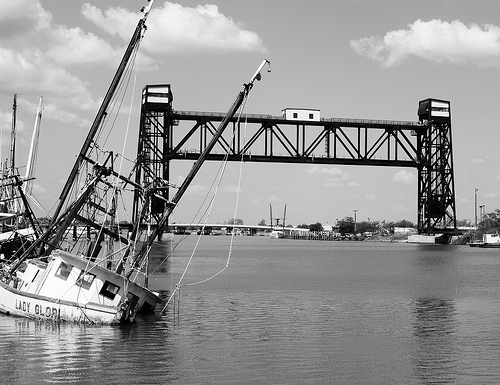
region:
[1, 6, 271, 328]
broken ship half under water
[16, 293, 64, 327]
Boat is named lady glori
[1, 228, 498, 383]
water is dark and calm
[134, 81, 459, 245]
boat pier and crane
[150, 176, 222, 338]
Ropes dragging in water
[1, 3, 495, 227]
sky is light and few clouds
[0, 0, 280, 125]
clouds are white and fluffy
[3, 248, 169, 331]
boats are white with windows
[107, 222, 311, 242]
bridge in background skyline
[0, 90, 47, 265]
boat behind the broken boat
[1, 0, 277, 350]
The ship is sinking.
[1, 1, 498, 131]
White clouds in sky.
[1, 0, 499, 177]
White clouds are puffy.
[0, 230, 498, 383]
The water is calm.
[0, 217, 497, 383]
The water is serene.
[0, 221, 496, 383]
The water is tranquil.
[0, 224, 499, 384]
The water is sedate.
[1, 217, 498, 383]
The water is ripply.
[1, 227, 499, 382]
The water is pleasant.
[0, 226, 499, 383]
The water is subdued.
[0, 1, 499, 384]
calm clear water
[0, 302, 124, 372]
shadow of boat in water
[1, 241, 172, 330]
front boat looks about to sink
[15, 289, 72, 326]
Lady Glory written on side of boat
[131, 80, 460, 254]
Tall black iron bridge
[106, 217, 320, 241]
white bridge in background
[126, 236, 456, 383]
shadow of black bridge in water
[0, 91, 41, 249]
second boat tipped opposite direction of first boat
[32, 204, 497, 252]
view of trees in background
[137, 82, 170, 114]
black stripe in center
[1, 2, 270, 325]
sinking white fishing boat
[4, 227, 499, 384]
calm glassy water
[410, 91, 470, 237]
black metal framed tower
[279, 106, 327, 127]
small white watch building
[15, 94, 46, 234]
white sail boat mast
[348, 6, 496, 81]
puffy white cloud in the sky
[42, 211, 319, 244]
long bridge in the distance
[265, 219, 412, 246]
distant river bank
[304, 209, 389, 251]
small grouping of several trees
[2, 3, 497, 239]
mostly clear sky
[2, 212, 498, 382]
THE WATER REFLECTS THE TOWERS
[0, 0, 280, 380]
THE BOAT IS SINKING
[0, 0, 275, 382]
THE BOAT IS TILTED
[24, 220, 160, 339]
THE BOAT HAS WINDOWS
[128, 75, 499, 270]
THE TOWERS ARE METAL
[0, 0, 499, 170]
THE SKY HAS CLOUDS IN IT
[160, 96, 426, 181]
THE BRIDGE HAS PEOPLE ON IT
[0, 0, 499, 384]
THE IMAGE IS BLACK AND WHITE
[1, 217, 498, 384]
THE WATER IS CLEAR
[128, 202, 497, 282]
THE SHORE HAS TREES ON IT